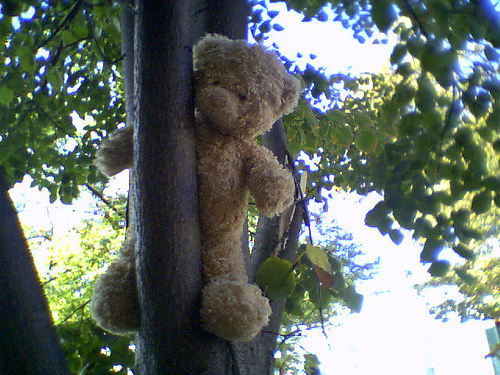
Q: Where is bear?
A: In tree.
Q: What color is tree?
A: Green.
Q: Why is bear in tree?
A: It was put up there.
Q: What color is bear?
A: Brown.